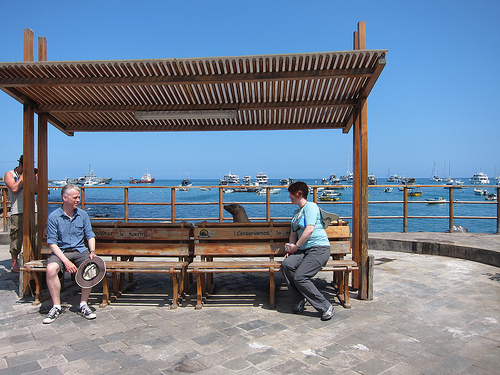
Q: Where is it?
A: This is at the harbor.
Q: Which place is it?
A: It is a harbor.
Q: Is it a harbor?
A: Yes, it is a harbor.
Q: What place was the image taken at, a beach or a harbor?
A: It was taken at a harbor.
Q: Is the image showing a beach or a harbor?
A: It is showing a harbor.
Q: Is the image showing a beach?
A: No, the picture is showing a harbor.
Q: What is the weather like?
A: It is clear.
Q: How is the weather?
A: It is clear.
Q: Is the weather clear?
A: Yes, it is clear.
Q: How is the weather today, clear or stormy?
A: It is clear.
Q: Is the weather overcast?
A: No, it is clear.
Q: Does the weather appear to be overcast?
A: No, it is clear.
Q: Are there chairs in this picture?
A: No, there are no chairs.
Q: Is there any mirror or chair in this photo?
A: No, there are no chairs or mirrors.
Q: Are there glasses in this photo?
A: No, there are no glasses.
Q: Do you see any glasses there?
A: No, there are no glasses.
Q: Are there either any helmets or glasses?
A: No, there are no glasses or helmets.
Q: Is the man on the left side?
A: Yes, the man is on the left of the image.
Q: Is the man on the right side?
A: No, the man is on the left of the image.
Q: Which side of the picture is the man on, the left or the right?
A: The man is on the left of the image.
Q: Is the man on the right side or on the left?
A: The man is on the left of the image.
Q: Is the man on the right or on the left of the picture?
A: The man is on the left of the image.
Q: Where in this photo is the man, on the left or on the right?
A: The man is on the left of the image.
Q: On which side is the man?
A: The man is on the left of the image.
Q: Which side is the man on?
A: The man is on the left of the image.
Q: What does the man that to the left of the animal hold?
A: The man holds the hat.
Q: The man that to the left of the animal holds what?
A: The man holds the hat.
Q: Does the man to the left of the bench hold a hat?
A: Yes, the man holds a hat.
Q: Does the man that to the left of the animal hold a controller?
A: No, the man holds a hat.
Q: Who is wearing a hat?
A: The man is wearing a hat.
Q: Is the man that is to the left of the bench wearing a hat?
A: Yes, the man is wearing a hat.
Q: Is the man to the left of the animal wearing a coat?
A: No, the man is wearing a hat.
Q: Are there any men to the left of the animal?
A: Yes, there is a man to the left of the animal.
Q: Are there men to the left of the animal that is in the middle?
A: Yes, there is a man to the left of the animal.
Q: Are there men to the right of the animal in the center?
A: No, the man is to the left of the animal.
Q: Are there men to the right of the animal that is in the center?
A: No, the man is to the left of the animal.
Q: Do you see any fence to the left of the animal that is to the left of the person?
A: No, there is a man to the left of the animal.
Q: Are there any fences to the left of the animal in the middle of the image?
A: No, there is a man to the left of the animal.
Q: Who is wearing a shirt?
A: The man is wearing a shirt.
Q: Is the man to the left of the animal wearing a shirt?
A: Yes, the man is wearing a shirt.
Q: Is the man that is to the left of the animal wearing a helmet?
A: No, the man is wearing a shirt.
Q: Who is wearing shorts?
A: The man is wearing shorts.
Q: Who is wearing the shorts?
A: The man is wearing shorts.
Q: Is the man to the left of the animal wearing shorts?
A: Yes, the man is wearing shorts.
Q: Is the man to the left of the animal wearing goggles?
A: No, the man is wearing shorts.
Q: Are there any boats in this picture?
A: Yes, there is a boat.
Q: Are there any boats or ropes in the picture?
A: Yes, there is a boat.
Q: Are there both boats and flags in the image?
A: No, there is a boat but no flags.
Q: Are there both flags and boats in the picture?
A: No, there is a boat but no flags.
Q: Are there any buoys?
A: No, there are no buoys.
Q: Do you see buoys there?
A: No, there are no buoys.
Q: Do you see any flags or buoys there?
A: No, there are no buoys or flags.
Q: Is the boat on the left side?
A: Yes, the boat is on the left of the image.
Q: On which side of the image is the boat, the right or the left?
A: The boat is on the left of the image.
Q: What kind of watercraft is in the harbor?
A: The watercraft is a boat.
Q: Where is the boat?
A: The boat is in the harbor.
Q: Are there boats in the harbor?
A: Yes, there is a boat in the harbor.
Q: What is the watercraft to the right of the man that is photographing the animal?
A: The watercraft is a boat.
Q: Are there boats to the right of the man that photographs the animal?
A: Yes, there is a boat to the right of the man.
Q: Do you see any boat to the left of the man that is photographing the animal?
A: No, the boat is to the right of the man.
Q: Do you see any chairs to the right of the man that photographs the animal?
A: No, there is a boat to the right of the man.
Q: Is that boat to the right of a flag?
A: No, the boat is to the right of the man.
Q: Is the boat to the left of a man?
A: No, the boat is to the right of a man.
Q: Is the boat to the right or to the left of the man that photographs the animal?
A: The boat is to the right of the man.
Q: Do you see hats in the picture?
A: Yes, there is a hat.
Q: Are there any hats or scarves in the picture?
A: Yes, there is a hat.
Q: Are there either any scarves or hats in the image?
A: Yes, there is a hat.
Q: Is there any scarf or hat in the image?
A: Yes, there is a hat.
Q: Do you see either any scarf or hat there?
A: Yes, there is a hat.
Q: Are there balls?
A: No, there are no balls.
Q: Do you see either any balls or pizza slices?
A: No, there are no balls or pizza slices.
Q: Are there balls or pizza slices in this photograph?
A: No, there are no balls or pizza slices.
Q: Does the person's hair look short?
A: Yes, the hair is short.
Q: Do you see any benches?
A: Yes, there is a bench.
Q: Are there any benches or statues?
A: Yes, there is a bench.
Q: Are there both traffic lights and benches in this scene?
A: No, there is a bench but no traffic lights.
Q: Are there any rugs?
A: No, there are no rugs.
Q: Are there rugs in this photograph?
A: No, there are no rugs.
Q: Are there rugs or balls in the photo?
A: No, there are no rugs or balls.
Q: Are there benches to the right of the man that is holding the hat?
A: Yes, there is a bench to the right of the man.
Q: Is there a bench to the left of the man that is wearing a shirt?
A: No, the bench is to the right of the man.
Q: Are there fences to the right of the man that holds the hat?
A: No, there is a bench to the right of the man.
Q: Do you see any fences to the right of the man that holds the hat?
A: No, there is a bench to the right of the man.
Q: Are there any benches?
A: Yes, there is a bench.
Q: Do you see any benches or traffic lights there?
A: Yes, there is a bench.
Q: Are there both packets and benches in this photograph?
A: No, there is a bench but no packets.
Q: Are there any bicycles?
A: No, there are no bicycles.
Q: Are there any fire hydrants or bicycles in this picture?
A: No, there are no bicycles or fire hydrants.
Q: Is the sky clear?
A: Yes, the sky is clear.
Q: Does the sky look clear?
A: Yes, the sky is clear.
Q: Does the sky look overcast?
A: No, the sky is clear.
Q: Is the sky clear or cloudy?
A: The sky is clear.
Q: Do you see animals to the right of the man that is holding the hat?
A: Yes, there is an animal to the right of the man.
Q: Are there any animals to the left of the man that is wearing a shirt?
A: No, the animal is to the right of the man.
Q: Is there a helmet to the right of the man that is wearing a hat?
A: No, there is an animal to the right of the man.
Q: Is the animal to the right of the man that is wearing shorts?
A: Yes, the animal is to the right of the man.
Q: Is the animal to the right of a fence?
A: No, the animal is to the right of the man.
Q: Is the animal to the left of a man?
A: No, the animal is to the right of a man.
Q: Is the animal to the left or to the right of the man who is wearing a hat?
A: The animal is to the right of the man.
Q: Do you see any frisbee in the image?
A: No, there are no frisbees.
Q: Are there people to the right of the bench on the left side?
A: Yes, there is a person to the right of the bench.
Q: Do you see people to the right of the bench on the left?
A: Yes, there is a person to the right of the bench.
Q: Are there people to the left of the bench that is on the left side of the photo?
A: No, the person is to the right of the bench.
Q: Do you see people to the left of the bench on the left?
A: No, the person is to the right of the bench.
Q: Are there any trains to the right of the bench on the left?
A: No, there is a person to the right of the bench.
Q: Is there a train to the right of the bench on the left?
A: No, there is a person to the right of the bench.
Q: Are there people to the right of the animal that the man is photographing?
A: Yes, there is a person to the right of the animal.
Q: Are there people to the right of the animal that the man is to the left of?
A: Yes, there is a person to the right of the animal.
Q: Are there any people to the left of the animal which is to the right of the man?
A: No, the person is to the right of the animal.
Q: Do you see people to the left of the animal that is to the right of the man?
A: No, the person is to the right of the animal.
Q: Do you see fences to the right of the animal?
A: No, there is a person to the right of the animal.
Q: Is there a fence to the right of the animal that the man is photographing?
A: No, there is a person to the right of the animal.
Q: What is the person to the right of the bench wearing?
A: The person is wearing a shirt.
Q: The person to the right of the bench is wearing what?
A: The person is wearing a shirt.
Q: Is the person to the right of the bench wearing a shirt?
A: Yes, the person is wearing a shirt.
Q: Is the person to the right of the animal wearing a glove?
A: No, the person is wearing a shirt.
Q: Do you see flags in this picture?
A: No, there are no flags.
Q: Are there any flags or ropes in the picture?
A: No, there are no flags or ropes.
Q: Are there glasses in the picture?
A: No, there are no glasses.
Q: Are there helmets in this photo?
A: No, there are no helmets.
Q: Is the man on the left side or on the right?
A: The man is on the left of the image.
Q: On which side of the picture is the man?
A: The man is on the left of the image.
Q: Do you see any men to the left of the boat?
A: Yes, there is a man to the left of the boat.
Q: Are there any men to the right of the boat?
A: No, the man is to the left of the boat.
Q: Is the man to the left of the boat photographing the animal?
A: Yes, the man is photographing the animal.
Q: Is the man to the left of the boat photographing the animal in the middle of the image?
A: Yes, the man is photographing the animal.